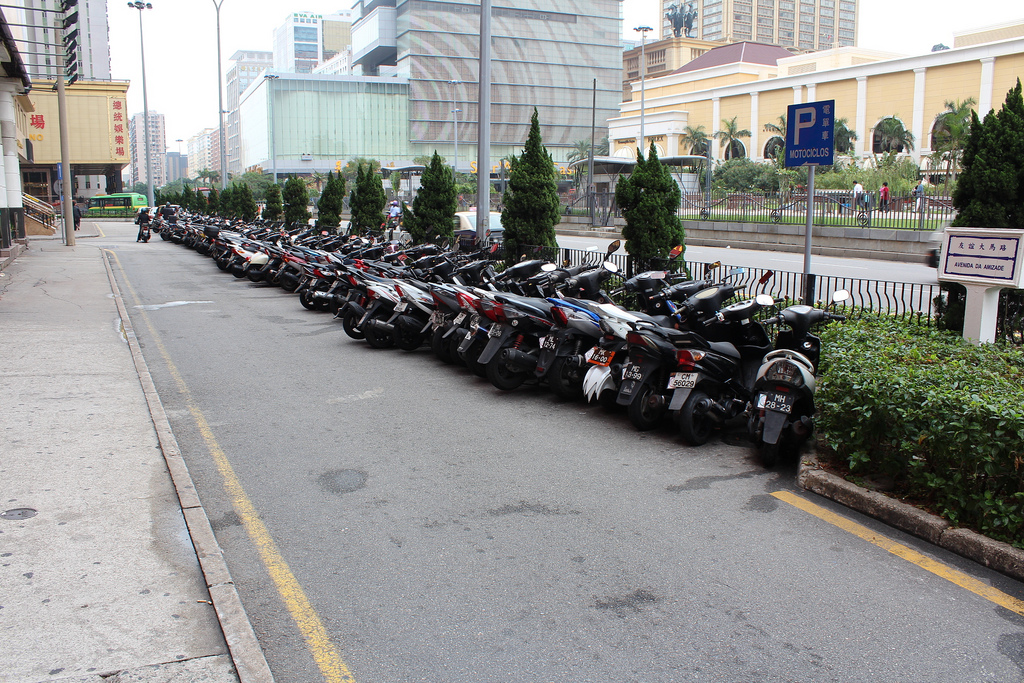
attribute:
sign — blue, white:
[769, 92, 847, 175]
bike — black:
[745, 273, 845, 487]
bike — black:
[652, 256, 789, 464]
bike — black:
[587, 243, 745, 432]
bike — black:
[464, 225, 648, 411]